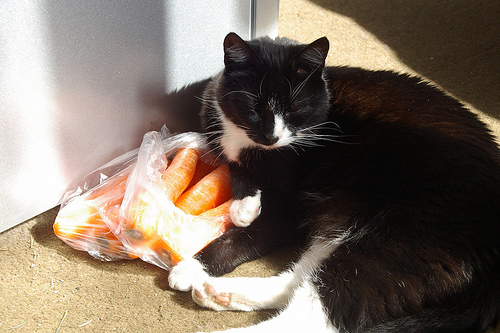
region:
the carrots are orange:
[51, 120, 253, 293]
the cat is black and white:
[169, 12, 499, 328]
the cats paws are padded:
[191, 277, 242, 322]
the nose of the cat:
[260, 125, 295, 153]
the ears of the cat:
[294, 32, 339, 63]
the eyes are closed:
[277, 92, 317, 120]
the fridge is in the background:
[0, 4, 291, 229]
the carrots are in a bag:
[40, 123, 246, 280]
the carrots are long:
[43, 128, 250, 265]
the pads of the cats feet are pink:
[191, 282, 238, 310]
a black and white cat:
[141, 18, 463, 310]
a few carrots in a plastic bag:
[54, 116, 229, 266]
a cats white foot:
[173, 22, 365, 229]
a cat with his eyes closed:
[205, 68, 329, 135]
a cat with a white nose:
[241, 72, 317, 162]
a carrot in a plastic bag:
[119, 150, 216, 228]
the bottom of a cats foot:
[188, 277, 250, 305]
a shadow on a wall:
[0, 32, 185, 137]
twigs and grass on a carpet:
[1, 286, 165, 331]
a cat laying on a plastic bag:
[45, 32, 464, 282]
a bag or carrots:
[37, 142, 237, 265]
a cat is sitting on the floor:
[166, 55, 494, 331]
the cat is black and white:
[196, 95, 328, 205]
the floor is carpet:
[14, 235, 196, 331]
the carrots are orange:
[171, 153, 245, 237]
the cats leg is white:
[197, 253, 337, 330]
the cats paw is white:
[160, 253, 215, 290]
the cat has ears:
[215, 32, 327, 73]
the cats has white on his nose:
[262, 109, 286, 144]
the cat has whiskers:
[191, 123, 342, 164]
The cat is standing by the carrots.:
[160, 30, 477, 288]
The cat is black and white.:
[216, 47, 446, 299]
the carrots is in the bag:
[76, 154, 251, 278]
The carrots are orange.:
[92, 146, 282, 253]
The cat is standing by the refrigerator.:
[31, 27, 321, 144]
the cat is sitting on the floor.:
[224, 33, 416, 313]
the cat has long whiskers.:
[207, 112, 348, 157]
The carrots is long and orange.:
[109, 129, 211, 250]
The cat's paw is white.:
[191, 269, 339, 327]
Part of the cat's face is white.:
[278, 108, 304, 156]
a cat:
[181, 26, 488, 328]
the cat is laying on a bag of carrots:
[187, 16, 499, 325]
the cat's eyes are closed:
[173, 11, 495, 329]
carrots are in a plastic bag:
[46, 125, 265, 268]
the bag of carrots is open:
[48, 127, 258, 274]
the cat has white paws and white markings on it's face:
[188, 28, 495, 325]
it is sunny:
[18, 3, 493, 330]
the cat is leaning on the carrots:
[53, 16, 495, 331]